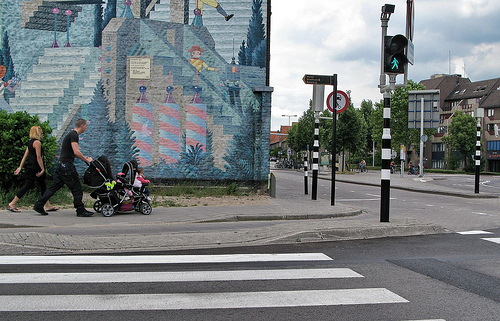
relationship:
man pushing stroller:
[30, 111, 87, 214] [76, 158, 162, 218]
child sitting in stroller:
[133, 168, 152, 201] [82, 151, 153, 221]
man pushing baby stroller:
[33, 118, 95, 218] [83, 155, 153, 217]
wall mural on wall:
[0, 0, 272, 180] [0, 0, 270, 182]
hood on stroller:
[82, 156, 110, 188] [82, 151, 153, 221]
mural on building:
[3, 0, 267, 175] [0, 1, 273, 194]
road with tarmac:
[0, 249, 496, 319] [0, 223, 477, 319]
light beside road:
[381, 32, 408, 75] [0, 227, 497, 318]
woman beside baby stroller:
[6, 126, 60, 213] [83, 155, 153, 217]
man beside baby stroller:
[33, 118, 95, 218] [83, 155, 153, 217]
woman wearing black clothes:
[7, 125, 57, 214] [13, 138, 47, 201]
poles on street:
[298, 35, 488, 229] [270, 162, 497, 258]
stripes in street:
[1, 250, 448, 319] [0, 170, 495, 316]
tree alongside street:
[0, 101, 70, 202] [8, 231, 495, 319]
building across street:
[412, 75, 486, 190] [269, 149, 436, 214]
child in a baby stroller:
[89, 142, 149, 207] [83, 155, 153, 217]